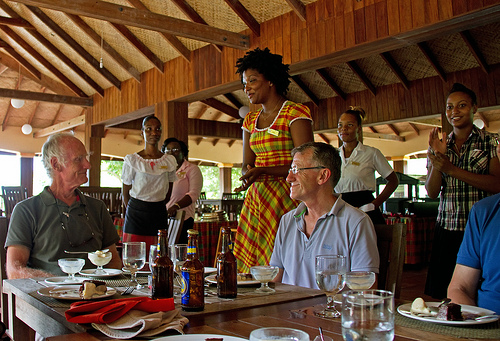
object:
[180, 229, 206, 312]
bottle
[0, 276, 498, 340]
table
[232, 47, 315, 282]
waitress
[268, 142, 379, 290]
man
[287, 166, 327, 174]
glasses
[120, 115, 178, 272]
people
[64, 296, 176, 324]
napkin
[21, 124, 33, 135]
light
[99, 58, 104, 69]
light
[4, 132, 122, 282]
guy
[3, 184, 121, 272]
shirt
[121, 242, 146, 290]
glass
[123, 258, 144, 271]
water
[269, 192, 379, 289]
shirt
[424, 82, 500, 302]
wom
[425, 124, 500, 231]
shirt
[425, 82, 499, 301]
woman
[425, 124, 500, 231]
colorfully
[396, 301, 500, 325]
plate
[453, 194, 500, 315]
shirt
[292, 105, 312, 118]
red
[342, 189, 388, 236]
apron